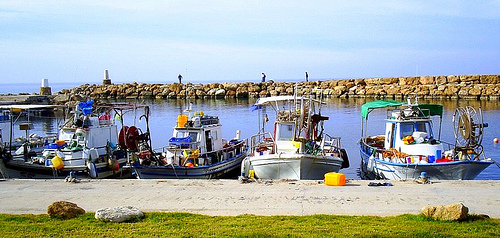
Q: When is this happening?
A: During the day.